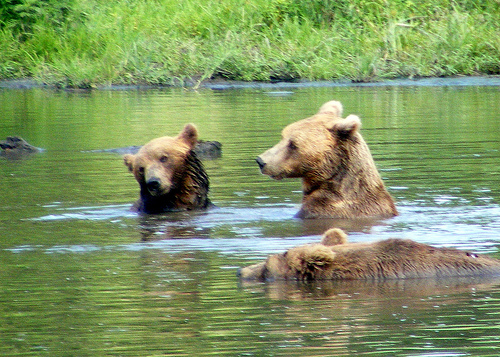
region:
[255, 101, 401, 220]
A brown bear in water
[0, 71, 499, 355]
Green ripling water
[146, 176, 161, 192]
Black nose of bear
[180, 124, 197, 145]
Ear of bear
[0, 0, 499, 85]
Green foilage in back ground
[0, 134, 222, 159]
A peice of drift wood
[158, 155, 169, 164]
Left eye of bear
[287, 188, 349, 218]
Shoulder of brown bear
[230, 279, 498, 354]
Reflection of brown bear in water.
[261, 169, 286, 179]
Mouth of a bear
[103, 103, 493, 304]
a group of bears swimming in a lake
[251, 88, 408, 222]
a bear in lake water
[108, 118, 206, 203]
the face of a bear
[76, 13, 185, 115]
small shrubs next to a lake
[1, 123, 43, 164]
the back of a bear's head in lake water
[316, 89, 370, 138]
bear ears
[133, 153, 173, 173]
a bear's two eyes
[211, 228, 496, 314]
the back of a large bear swimming in a lake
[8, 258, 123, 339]
lake water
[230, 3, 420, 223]
a bear in a lake with green shrubbery in the background.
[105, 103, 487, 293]
a group of bears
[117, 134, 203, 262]
a bear in water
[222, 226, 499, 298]
a bear lying in water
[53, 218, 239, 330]
a reflection in the water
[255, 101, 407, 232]
a bear standing in water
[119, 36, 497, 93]
a grassy bank line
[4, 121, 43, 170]
a rock in water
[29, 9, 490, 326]
bears swimming in water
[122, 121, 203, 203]
head of a bear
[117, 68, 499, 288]
brown bears in the water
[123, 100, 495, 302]
three bears playing in the water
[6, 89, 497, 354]
green colored water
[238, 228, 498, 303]
a brown bear laying in the water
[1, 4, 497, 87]
a bank with green grass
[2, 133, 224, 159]
two rocks protruding from the water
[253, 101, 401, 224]
a large brown bear looking to the right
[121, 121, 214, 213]
a brown bear with wet fur on it's neck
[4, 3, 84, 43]
leaves of a tree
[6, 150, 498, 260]
sunlight reflecting on the water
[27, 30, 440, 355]
Three bears in the river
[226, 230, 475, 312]
Bear swimming in the river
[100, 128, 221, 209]
Bear with head cocked to left side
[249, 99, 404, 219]
Bear standing in water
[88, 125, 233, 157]
A large rock behind bears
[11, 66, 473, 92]
The river bank behind bears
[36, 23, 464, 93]
Bushes along bank on river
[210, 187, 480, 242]
Ripples in the water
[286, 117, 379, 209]
Light brown bear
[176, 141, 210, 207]
Dark spot on side of bears neck